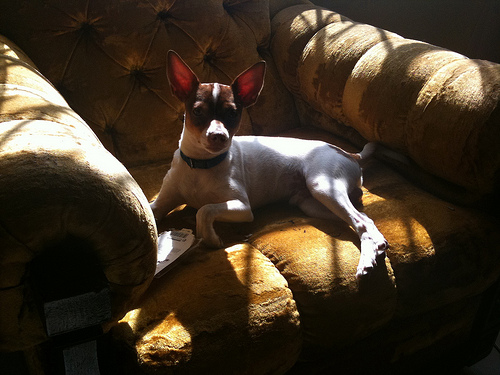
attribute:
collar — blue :
[171, 144, 231, 167]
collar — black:
[175, 146, 233, 171]